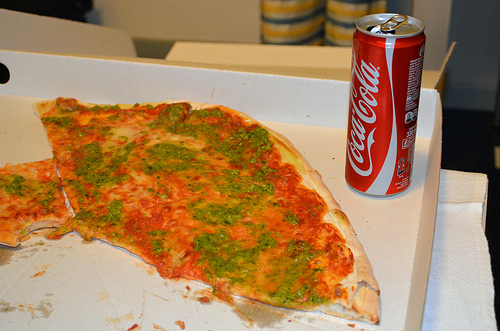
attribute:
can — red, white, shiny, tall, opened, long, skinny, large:
[343, 9, 420, 199]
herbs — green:
[140, 143, 191, 176]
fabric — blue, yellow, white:
[260, 1, 409, 52]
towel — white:
[419, 160, 495, 330]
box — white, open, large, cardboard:
[1, 47, 446, 330]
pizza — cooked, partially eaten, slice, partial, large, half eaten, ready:
[1, 97, 381, 327]